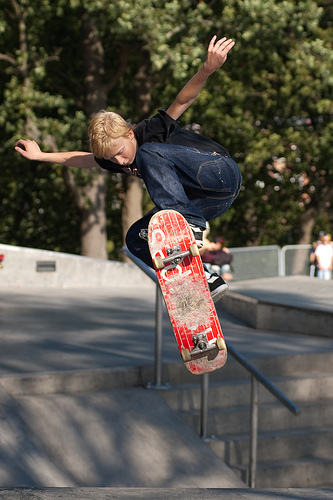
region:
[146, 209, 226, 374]
a scratched up red skateboard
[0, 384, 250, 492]
a grey concrete skateboard ramp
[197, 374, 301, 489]
a metal skateboard rail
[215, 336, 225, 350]
white polyurethane skateboard wheels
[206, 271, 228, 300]
a black and white skateboard shoe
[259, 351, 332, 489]
grey concrete steps next to the hand rail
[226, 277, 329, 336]
a low concrete flat jump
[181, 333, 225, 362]
the wheels and truck of the skateboard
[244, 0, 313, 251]
large trees behind the skate park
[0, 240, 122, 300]
a concrete wall along the skate park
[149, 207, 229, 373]
A red skateboard in the air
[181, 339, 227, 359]
Back wheels on a skateboard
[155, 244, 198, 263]
Front wheels on a skateboard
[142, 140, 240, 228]
Blue jeans on a boy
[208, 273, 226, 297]
Black shoe with white sole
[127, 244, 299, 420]
Metal hand rail near a ramp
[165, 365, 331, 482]
Cement steps in a park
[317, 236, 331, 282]
Person in white shirt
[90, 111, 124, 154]
Blonde hair on a boy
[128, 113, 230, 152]
Black t-shirt on a boy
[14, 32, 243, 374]
A kid on a skateboard.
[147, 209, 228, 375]
Red and white skateboard.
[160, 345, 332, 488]
Some gray cement steps.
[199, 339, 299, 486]
A gray metal rail.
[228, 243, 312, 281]
An area of fencing.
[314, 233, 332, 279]
A person wearing white.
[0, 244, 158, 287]
A gray cement wall.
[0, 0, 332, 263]
A background of trees.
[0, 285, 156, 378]
A flat cement area.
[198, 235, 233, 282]
People in the background.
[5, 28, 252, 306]
skater has blonde hair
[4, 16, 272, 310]
boy has extended arms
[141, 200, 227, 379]
skateboard is color red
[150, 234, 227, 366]
wheels of skateboard are white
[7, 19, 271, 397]
skater is on the air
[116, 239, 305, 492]
the rail on side the ramp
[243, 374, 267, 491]
the baluster of rail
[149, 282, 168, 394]
the baluster of rail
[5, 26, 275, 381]
boy has black shirt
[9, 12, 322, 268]
tree behind a skater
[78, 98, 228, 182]
man wearing dark short sleeved shirt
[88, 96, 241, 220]
man wearing dark blue jeans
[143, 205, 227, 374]
bottom of large red skateboard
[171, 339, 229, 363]
two light colored skateboard wheels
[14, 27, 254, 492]
one skateboarder jumping over ramp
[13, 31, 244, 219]
one partially sunlit jumping man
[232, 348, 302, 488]
sloping light colored metal railing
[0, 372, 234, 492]
partially shaded skateboard ramp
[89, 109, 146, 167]
man with short blond hair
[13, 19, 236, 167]
one Caucasian man with arms outstretched